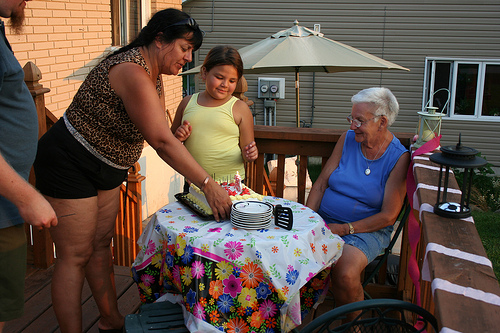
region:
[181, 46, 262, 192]
Girl in yellow shirt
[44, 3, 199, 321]
Woman in leopard print shirt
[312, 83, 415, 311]
Grandma in blue shirt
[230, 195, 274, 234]
stack of plates on table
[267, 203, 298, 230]
black spatulla on table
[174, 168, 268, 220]
Birthday cake on table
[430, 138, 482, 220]
Black lantern on deck rail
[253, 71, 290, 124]
Utility meter on adjacent building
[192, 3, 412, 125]
Tan patio umbrella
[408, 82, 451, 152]
Light green lantern on deck rail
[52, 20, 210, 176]
woman wearing cheetah print shirt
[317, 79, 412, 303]
older woman wearing blue sleeveless shirt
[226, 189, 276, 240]
stack of white plates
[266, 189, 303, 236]
black spatula for food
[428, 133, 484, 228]
black candle holder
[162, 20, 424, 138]
open tan umbrella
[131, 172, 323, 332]
floral table cloth for table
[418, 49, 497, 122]
white trim on window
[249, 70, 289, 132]
silver water meter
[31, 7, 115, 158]
orange brick wall for house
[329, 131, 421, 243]
the shirt is blue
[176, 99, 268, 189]
the shirt is yellow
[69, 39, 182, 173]
the shirt is a cheetah pattern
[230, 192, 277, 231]
the plates are white and black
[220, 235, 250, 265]
the flower is pink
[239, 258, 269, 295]
the flower is orange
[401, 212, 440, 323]
the streamer is pink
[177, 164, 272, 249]
the cake has yellow on it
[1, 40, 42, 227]
the shirt is bluish grey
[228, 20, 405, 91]
the umbrella is a cream color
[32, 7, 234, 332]
woman setting down birthday cake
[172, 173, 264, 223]
birthday cake with candles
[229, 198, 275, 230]
empty dessert plates on table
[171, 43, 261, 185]
young girl looking at cake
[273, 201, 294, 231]
pancake turner for lifting cake slices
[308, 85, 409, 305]
elderly woman with white hair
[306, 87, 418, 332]
elderly woman wearing blue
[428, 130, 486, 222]
lantern on brick wall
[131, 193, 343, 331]
table with flowered tablecloth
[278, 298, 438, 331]
back of black metal chair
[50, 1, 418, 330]
the people are celebrating a birthday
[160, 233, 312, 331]
a floral tablecloth covering the table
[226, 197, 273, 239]
a stack of plates on the table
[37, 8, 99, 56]
the side of the house is covered with brick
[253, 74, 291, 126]
a utility box on the side of the house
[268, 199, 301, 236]
a spatula for serving the cake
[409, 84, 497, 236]
lanterns sitting on the sides of the deck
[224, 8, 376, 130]
an umbrella for sitting under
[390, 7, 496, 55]
gray siding covering the house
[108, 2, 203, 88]
a woman with sunglasses on the top of her head